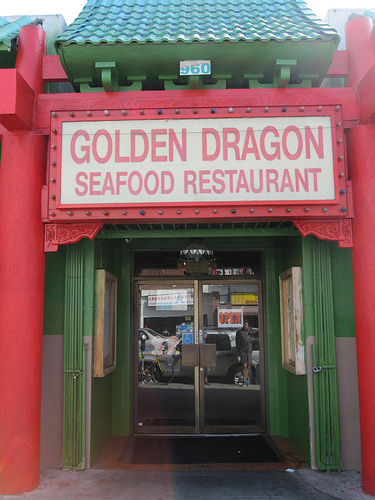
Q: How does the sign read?
A: Golden Dragon Seafood Restaurant.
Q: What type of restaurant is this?
A: Seafood.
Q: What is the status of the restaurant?
A: Open.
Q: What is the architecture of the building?
A: Far East.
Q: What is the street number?
A: 960.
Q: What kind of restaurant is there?
A: Seafood.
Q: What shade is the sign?
A: Red and white.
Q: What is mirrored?
A: Doors.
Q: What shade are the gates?
A: Green.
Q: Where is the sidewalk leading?
A: Restaurant.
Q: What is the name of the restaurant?
A: Golden Dragon.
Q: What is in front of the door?
A: Mat.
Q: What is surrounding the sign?
A: Lights.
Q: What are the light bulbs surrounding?
A: Sign.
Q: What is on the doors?
A: Locks.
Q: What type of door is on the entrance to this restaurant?
A: A glass door.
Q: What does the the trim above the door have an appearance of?
A: A green appearance.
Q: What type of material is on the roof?
A: Clay tile design.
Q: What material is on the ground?
A: Concrete.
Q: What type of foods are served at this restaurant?
A: Seafood.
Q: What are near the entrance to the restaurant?
A: Pictures.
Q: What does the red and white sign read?
A: Golden Dragon Seafood Restaurant.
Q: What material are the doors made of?
A: Glass.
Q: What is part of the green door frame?
A: An opened gate.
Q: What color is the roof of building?
A: Green.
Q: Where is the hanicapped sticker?
A: On the door.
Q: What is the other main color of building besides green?
A: Red.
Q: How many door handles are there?
A: Two.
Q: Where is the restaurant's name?
A: Above the door.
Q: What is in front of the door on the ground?
A: A mat.